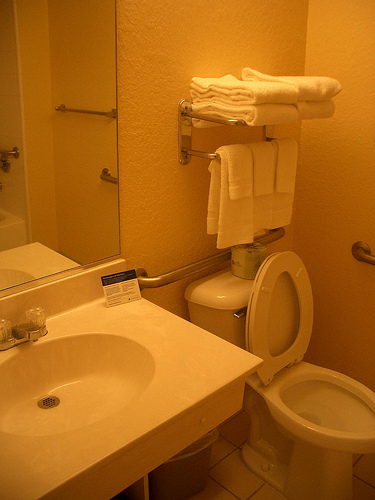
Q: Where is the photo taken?
A: Bathroom.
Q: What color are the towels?
A: White.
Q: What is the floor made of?
A: Tile.